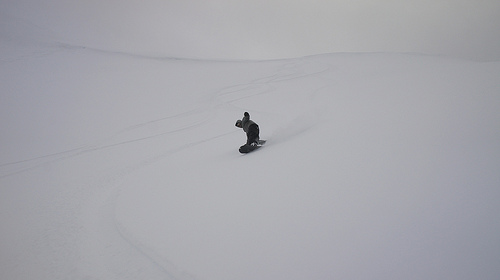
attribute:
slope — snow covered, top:
[24, 11, 474, 101]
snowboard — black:
[237, 138, 266, 155]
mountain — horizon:
[5, 32, 487, 279]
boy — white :
[233, 110, 268, 154]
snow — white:
[46, 100, 301, 258]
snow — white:
[2, 0, 499, 276]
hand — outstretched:
[243, 108, 250, 117]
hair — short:
[234, 117, 241, 127]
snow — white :
[4, 11, 218, 277]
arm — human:
[212, 105, 281, 165]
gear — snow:
[238, 110, 259, 148]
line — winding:
[7, 40, 484, 65]